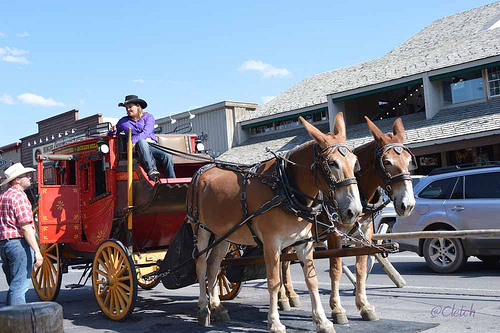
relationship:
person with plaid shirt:
[4, 160, 44, 305] [0, 185, 37, 238]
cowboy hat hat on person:
[1, 159, 36, 184] [0, 160, 46, 313]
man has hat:
[111, 97, 178, 182] [118, 94, 148, 109]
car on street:
[388, 157, 498, 271] [1, 218, 496, 329]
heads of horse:
[294, 115, 420, 228] [251, 112, 413, 328]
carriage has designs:
[29, 129, 244, 321] [38, 188, 88, 243]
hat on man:
[121, 95, 146, 107] [121, 96, 171, 177]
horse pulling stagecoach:
[185, 110, 362, 331] [18, 121, 200, 307]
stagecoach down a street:
[18, 121, 200, 307] [2, 260, 499, 332]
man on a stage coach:
[103, 94, 178, 181] [33, 133, 245, 316]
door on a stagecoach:
[35, 151, 91, 243] [28, 122, 242, 323]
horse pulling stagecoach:
[190, 140, 360, 332] [20, 122, 188, 271]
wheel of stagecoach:
[75, 221, 177, 328] [10, 111, 344, 331]